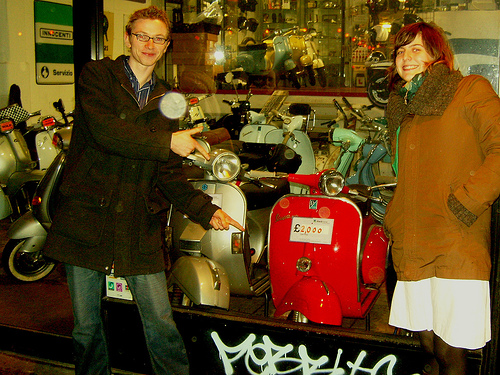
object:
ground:
[437, 127, 477, 166]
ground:
[406, 117, 446, 163]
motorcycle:
[166, 148, 290, 317]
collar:
[114, 54, 166, 120]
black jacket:
[42, 54, 222, 278]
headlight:
[317, 170, 345, 198]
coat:
[383, 63, 498, 281]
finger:
[187, 125, 205, 135]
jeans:
[66, 264, 189, 374]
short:
[387, 276, 491, 349]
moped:
[248, 168, 397, 332]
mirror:
[163, 0, 404, 98]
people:
[383, 21, 498, 374]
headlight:
[207, 148, 242, 183]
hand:
[170, 126, 212, 161]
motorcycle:
[344, 127, 401, 225]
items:
[263, 28, 303, 90]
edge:
[402, 272, 469, 282]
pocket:
[138, 188, 170, 255]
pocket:
[50, 179, 116, 247]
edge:
[387, 320, 432, 331]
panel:
[99, 299, 421, 374]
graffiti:
[205, 330, 397, 374]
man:
[39, 6, 246, 374]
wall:
[187, 93, 385, 120]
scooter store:
[0, 0, 500, 374]